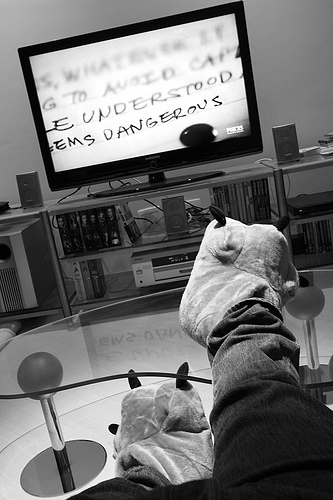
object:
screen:
[16, 0, 263, 184]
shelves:
[0, 164, 327, 311]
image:
[224, 121, 244, 134]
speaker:
[161, 196, 191, 238]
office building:
[0, 0, 331, 499]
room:
[1, 0, 333, 499]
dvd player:
[128, 242, 205, 290]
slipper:
[176, 204, 298, 345]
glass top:
[0, 281, 325, 408]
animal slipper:
[113, 361, 214, 486]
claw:
[174, 361, 191, 390]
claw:
[128, 368, 140, 388]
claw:
[106, 425, 118, 433]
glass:
[100, 315, 149, 349]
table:
[0, 0, 333, 500]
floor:
[0, 386, 98, 500]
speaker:
[1, 213, 55, 317]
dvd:
[210, 177, 273, 222]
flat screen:
[18, 0, 263, 190]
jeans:
[202, 298, 328, 500]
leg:
[202, 302, 333, 500]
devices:
[127, 195, 245, 292]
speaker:
[13, 170, 44, 208]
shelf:
[59, 193, 258, 263]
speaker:
[271, 123, 300, 165]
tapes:
[52, 203, 124, 259]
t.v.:
[16, 0, 265, 199]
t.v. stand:
[0, 144, 332, 332]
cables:
[183, 197, 209, 227]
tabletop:
[1, 142, 333, 231]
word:
[92, 91, 227, 141]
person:
[82, 199, 332, 500]